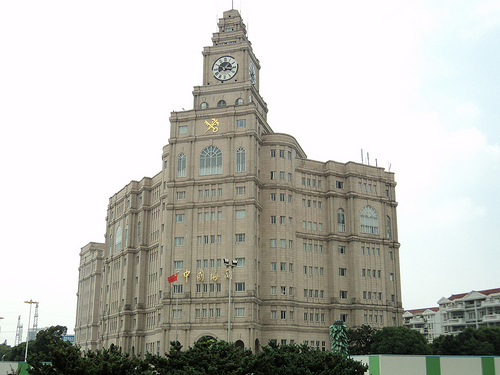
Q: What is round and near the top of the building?
A: A clock.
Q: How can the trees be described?
A: Green and leafy.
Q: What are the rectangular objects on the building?
A: Windows.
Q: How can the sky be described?
A: Cloudy.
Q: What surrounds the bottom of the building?
A: Trees.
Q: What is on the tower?
A: Clock.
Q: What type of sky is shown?
A: Partly cloudy.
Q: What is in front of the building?
A: Trees.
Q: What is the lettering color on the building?
A: Cold.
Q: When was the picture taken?
A: Daytime.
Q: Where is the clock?
A: Top of the building.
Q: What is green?
A: Tree.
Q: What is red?
A: Roof.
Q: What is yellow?
A: Flag.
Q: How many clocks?
A: One.